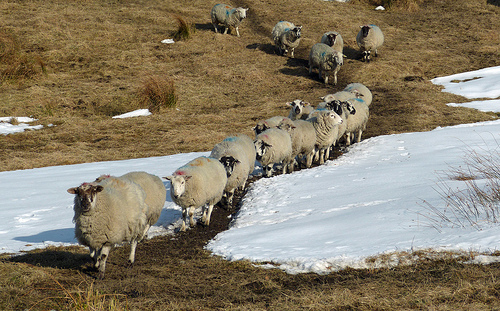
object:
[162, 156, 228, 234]
sheep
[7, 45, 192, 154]
field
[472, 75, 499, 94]
snow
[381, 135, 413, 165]
footprints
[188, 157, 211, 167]
spot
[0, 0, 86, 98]
grass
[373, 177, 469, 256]
hill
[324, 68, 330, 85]
legs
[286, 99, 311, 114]
head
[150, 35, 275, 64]
feeet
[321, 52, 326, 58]
wool